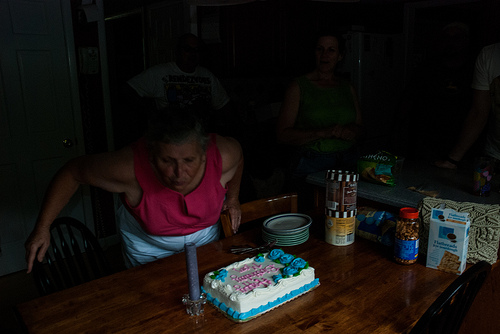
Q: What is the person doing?
A: Blowing out a candle.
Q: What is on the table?
A: A cake.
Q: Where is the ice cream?
A: Beside the cake.